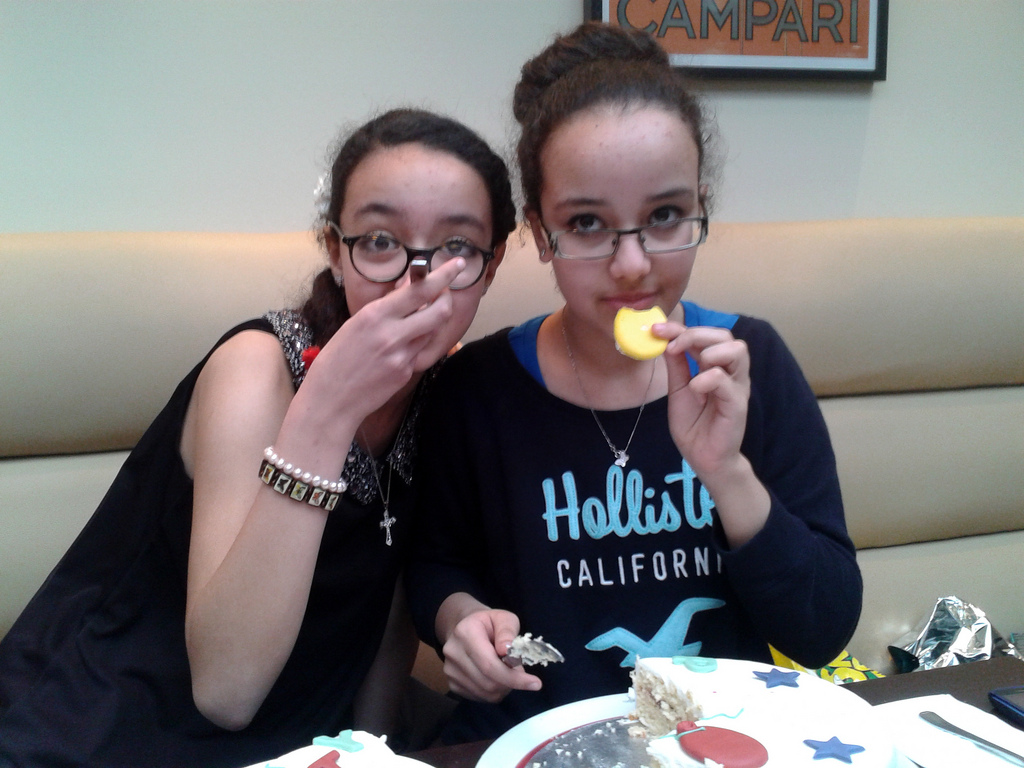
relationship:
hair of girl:
[510, 22, 701, 189] [388, 13, 873, 754]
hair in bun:
[510, 22, 701, 189] [524, 14, 676, 88]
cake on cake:
[504, 623, 556, 660] [501, 634, 566, 668]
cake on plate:
[621, 631, 881, 765] [473, 681, 686, 765]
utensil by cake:
[912, 699, 1021, 766] [632, 646, 894, 757]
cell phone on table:
[982, 675, 1021, 726] [872, 653, 1020, 733]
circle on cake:
[668, 715, 766, 766] [617, 642, 933, 763]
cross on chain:
[372, 500, 405, 549] [357, 422, 407, 507]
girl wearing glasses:
[0, 100, 523, 759] [332, 212, 492, 292]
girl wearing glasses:
[388, 13, 873, 754] [530, 191, 716, 254]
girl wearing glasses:
[388, 13, 873, 754] [521, 202, 709, 255]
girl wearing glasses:
[0, 100, 523, 759] [332, 223, 493, 299]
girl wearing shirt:
[388, 13, 873, 754] [400, 305, 862, 729]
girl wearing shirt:
[0, 100, 523, 759] [5, 309, 408, 761]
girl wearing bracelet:
[0, 100, 523, 759] [247, 440, 353, 520]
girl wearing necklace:
[388, 13, 873, 754] [573, 318, 662, 485]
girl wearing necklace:
[0, 100, 523, 759] [362, 405, 414, 544]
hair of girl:
[492, 17, 714, 207] [388, 13, 873, 754]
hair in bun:
[492, 17, 714, 207] [510, 27, 666, 113]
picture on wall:
[592, 3, 891, 84] [4, 5, 1022, 228]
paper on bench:
[871, 597, 1008, 682] [1, 205, 1022, 684]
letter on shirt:
[540, 470, 579, 542] [382, 299, 863, 765]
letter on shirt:
[556, 553, 582, 593] [400, 305, 862, 729]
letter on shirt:
[623, 494, 674, 530] [381, 297, 906, 743]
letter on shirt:
[654, 442, 712, 541] [400, 305, 862, 729]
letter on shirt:
[523, 453, 593, 551] [400, 305, 862, 729]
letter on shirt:
[581, 497, 606, 540] [400, 305, 862, 729]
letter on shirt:
[604, 460, 623, 550] [400, 305, 862, 729]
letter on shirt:
[619, 466, 645, 524] [400, 305, 862, 729]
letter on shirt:
[640, 490, 654, 539] [400, 305, 862, 729]